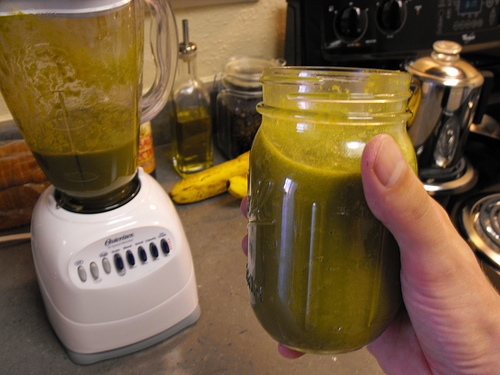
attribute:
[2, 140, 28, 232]
bread — sliced 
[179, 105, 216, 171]
oil — green 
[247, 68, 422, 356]
jar — green, liquid, glass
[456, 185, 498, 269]
burner — electric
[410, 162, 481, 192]
burner — electric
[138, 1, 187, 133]
handle — glass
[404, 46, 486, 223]
kettle — silver, tea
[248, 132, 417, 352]
salsa — green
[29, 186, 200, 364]
base — white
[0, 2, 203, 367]
blender — white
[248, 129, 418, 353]
liquid — green